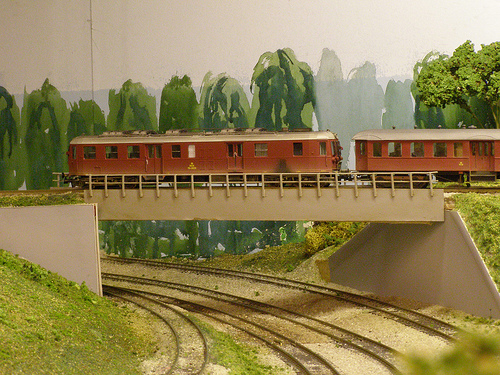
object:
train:
[62, 125, 500, 189]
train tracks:
[150, 298, 317, 375]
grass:
[0, 247, 160, 374]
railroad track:
[100, 290, 181, 374]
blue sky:
[0, 0, 498, 105]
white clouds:
[1, 0, 499, 96]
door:
[145, 144, 164, 175]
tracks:
[101, 283, 209, 374]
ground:
[0, 179, 499, 373]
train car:
[59, 127, 344, 189]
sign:
[187, 162, 197, 169]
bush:
[303, 223, 330, 257]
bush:
[327, 220, 359, 246]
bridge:
[50, 170, 445, 227]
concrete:
[0, 185, 499, 321]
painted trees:
[247, 46, 318, 133]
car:
[351, 125, 499, 190]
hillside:
[0, 248, 164, 374]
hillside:
[439, 189, 499, 296]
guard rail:
[81, 171, 439, 200]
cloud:
[1, 0, 499, 93]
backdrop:
[0, 0, 499, 263]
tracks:
[64, 186, 500, 192]